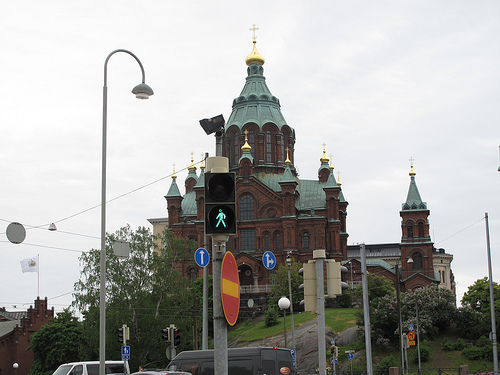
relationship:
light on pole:
[133, 89, 154, 104] [91, 48, 117, 373]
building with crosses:
[152, 2, 457, 298] [167, 10, 428, 177]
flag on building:
[15, 251, 41, 281] [4, 293, 59, 369]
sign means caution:
[215, 251, 248, 332] [223, 253, 247, 320]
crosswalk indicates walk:
[202, 206, 240, 242] [216, 207, 230, 231]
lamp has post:
[277, 288, 293, 315] [281, 310, 291, 356]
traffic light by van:
[159, 318, 180, 357] [167, 342, 299, 373]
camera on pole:
[198, 113, 233, 143] [213, 132, 225, 163]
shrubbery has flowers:
[365, 287, 498, 369] [420, 291, 429, 304]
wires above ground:
[2, 213, 205, 262] [12, 370, 34, 374]